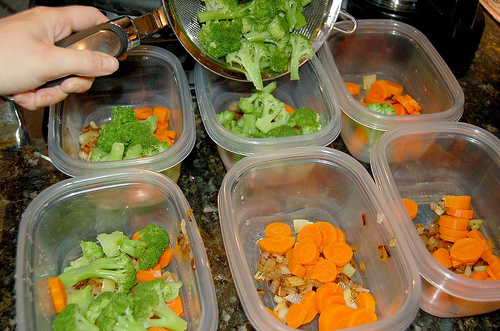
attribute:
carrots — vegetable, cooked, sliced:
[261, 215, 377, 323]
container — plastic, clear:
[219, 146, 425, 329]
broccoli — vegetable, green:
[60, 218, 175, 330]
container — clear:
[10, 168, 222, 327]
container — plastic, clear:
[372, 116, 499, 329]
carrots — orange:
[344, 65, 438, 113]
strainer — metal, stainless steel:
[56, 0, 359, 88]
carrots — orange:
[134, 100, 176, 147]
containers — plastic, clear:
[34, 9, 495, 331]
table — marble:
[3, 6, 499, 328]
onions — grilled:
[265, 222, 359, 309]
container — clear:
[196, 39, 347, 151]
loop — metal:
[332, 7, 356, 40]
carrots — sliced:
[285, 97, 299, 116]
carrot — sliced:
[296, 239, 316, 266]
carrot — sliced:
[48, 278, 65, 314]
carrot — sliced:
[454, 237, 482, 267]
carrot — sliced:
[155, 107, 171, 128]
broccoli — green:
[127, 119, 155, 161]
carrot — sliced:
[134, 104, 151, 123]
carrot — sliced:
[444, 194, 474, 210]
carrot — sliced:
[403, 197, 420, 219]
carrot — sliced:
[266, 221, 291, 244]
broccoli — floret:
[141, 223, 170, 253]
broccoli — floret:
[72, 251, 136, 285]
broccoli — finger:
[52, 305, 96, 331]